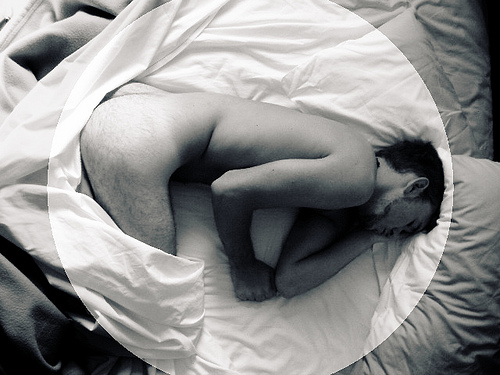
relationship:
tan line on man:
[75, 82, 176, 253] [81, 81, 446, 302]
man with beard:
[81, 81, 446, 302] [367, 200, 396, 236]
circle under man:
[47, 1, 454, 374] [81, 81, 446, 302]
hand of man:
[229, 259, 278, 302] [81, 81, 446, 302]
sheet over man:
[1, 2, 204, 372] [81, 81, 446, 302]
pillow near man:
[360, 155, 499, 374] [81, 81, 446, 302]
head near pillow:
[356, 139, 445, 239] [360, 155, 499, 374]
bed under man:
[1, 0, 499, 373] [81, 81, 446, 302]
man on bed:
[81, 81, 446, 302] [1, 0, 499, 373]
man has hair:
[81, 81, 446, 302] [377, 140, 443, 204]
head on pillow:
[356, 139, 445, 239] [360, 155, 499, 374]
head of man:
[356, 139, 445, 239] [81, 81, 446, 302]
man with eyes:
[81, 81, 446, 302] [404, 213, 416, 240]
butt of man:
[78, 81, 164, 171] [81, 81, 446, 302]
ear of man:
[404, 176, 432, 196] [81, 81, 446, 302]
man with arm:
[81, 81, 446, 302] [210, 154, 375, 312]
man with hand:
[81, 81, 446, 302] [229, 259, 278, 302]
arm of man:
[210, 154, 375, 312] [81, 81, 446, 302]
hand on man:
[229, 259, 278, 302] [81, 81, 446, 302]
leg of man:
[84, 164, 180, 256] [81, 81, 446, 302]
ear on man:
[404, 176, 432, 196] [81, 81, 446, 302]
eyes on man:
[404, 213, 416, 240] [81, 81, 446, 302]